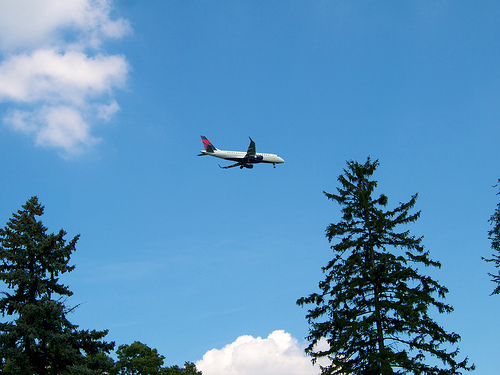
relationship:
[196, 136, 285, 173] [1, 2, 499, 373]
airplane in sky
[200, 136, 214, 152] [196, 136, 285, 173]
tail fin on airplane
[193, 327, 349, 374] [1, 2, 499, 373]
cloud in sky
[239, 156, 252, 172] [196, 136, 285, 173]
wheels on airplane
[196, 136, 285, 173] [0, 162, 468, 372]
airplane flying over trees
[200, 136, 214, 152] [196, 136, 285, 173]
tail fin of airplane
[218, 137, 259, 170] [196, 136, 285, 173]
wings of airplane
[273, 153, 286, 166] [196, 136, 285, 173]
nose of airplane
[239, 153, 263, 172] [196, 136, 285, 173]
engines of airplane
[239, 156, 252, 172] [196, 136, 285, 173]
wheels underneath airplane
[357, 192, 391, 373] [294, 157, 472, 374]
trunk of tree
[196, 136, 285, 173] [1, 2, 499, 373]
airplane flying through sky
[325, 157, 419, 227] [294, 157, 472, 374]
top of tree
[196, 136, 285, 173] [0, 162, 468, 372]
airplane flying trees